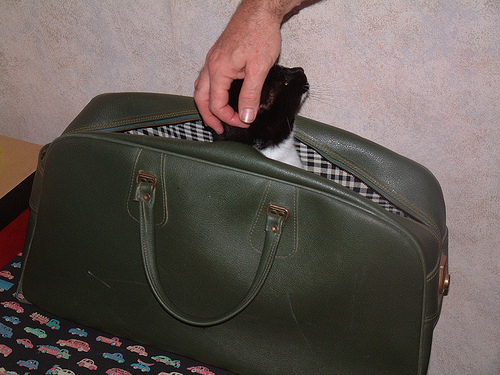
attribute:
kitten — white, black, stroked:
[206, 65, 309, 172]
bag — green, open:
[19, 93, 450, 374]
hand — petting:
[195, 17, 282, 135]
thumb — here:
[237, 63, 273, 124]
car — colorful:
[76, 358, 96, 371]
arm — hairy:
[238, 0, 308, 21]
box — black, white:
[0, 134, 43, 270]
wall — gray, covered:
[2, 0, 498, 374]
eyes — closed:
[255, 84, 278, 114]